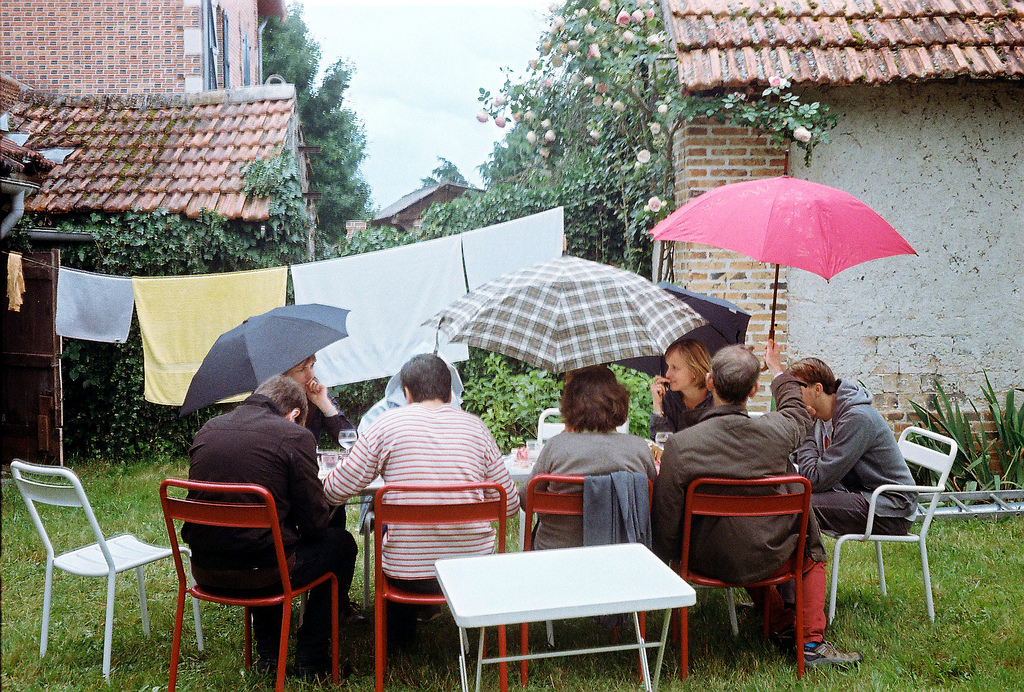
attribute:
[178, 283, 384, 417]
umbrella — open, black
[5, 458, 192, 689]
chair — empty, metal, white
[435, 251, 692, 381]
umbrella — plaid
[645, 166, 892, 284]
umbrella — open, red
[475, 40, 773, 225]
roses — pink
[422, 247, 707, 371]
umbrella — brown, white, checked, open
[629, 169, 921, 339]
umbrella — pink